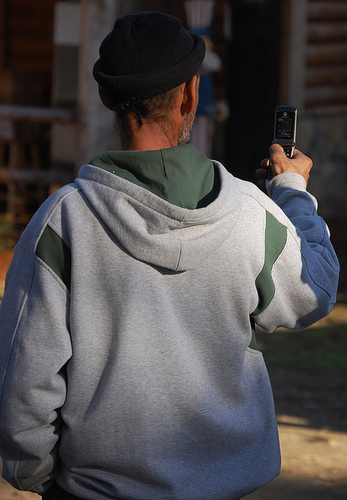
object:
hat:
[91, 11, 204, 102]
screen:
[274, 116, 293, 142]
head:
[89, 9, 205, 142]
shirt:
[4, 149, 335, 498]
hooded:
[75, 148, 239, 268]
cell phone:
[264, 101, 300, 181]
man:
[6, 5, 328, 498]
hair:
[91, 94, 194, 136]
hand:
[254, 138, 318, 199]